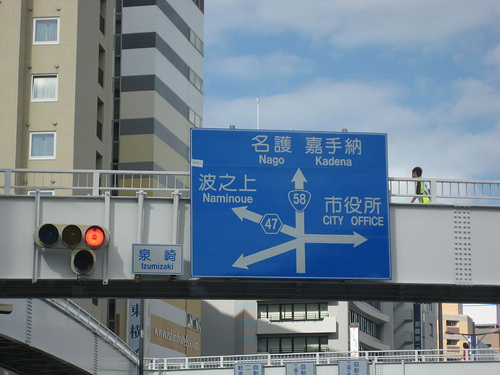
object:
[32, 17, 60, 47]
window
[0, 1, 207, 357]
building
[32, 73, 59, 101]
window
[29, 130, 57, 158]
window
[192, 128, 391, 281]
street sign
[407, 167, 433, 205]
man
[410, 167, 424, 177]
head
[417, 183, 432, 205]
jacket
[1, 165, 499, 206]
rail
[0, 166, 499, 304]
bridge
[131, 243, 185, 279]
street sign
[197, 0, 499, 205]
cloud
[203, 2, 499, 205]
sky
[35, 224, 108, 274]
traffic light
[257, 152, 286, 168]
letters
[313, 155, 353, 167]
letters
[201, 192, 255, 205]
letters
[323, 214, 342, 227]
letters